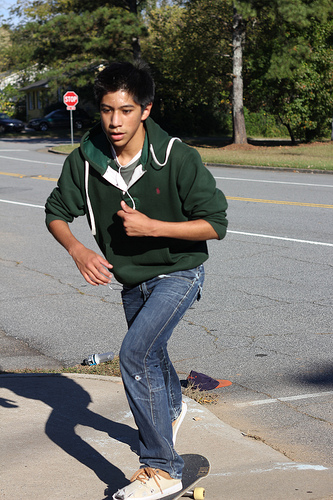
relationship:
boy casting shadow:
[46, 52, 227, 500] [1, 369, 140, 499]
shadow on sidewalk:
[1, 369, 140, 499] [0, 372, 332, 498]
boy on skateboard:
[46, 52, 227, 500] [81, 452, 206, 498]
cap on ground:
[185, 369, 234, 390] [3, 138, 331, 498]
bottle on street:
[79, 353, 114, 368] [1, 142, 330, 374]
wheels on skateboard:
[193, 485, 204, 497] [130, 454, 209, 498]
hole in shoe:
[116, 488, 129, 498] [111, 464, 184, 499]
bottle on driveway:
[82, 353, 100, 365] [1, 133, 333, 476]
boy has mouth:
[46, 52, 227, 500] [105, 129, 126, 142]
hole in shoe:
[113, 488, 129, 498] [111, 464, 184, 499]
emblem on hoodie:
[156, 187, 161, 194] [45, 116, 227, 285]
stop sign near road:
[62, 89, 80, 112] [1, 142, 332, 499]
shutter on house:
[32, 94, 39, 112] [21, 77, 56, 117]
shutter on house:
[25, 96, 30, 109] [21, 77, 56, 117]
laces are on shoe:
[128, 466, 158, 479] [113, 472, 185, 497]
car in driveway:
[25, 104, 90, 134] [1, 133, 55, 142]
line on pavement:
[249, 386, 329, 408] [167, 294, 330, 467]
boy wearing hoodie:
[40, 52, 234, 496] [42, 113, 228, 288]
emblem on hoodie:
[153, 184, 162, 195] [42, 113, 228, 288]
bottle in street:
[82, 353, 100, 365] [1, 250, 331, 379]